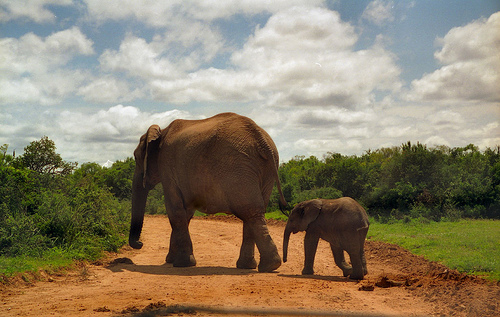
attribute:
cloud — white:
[147, 66, 264, 101]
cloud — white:
[410, 10, 497, 100]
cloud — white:
[236, 10, 360, 67]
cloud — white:
[359, 0, 415, 26]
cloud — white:
[1, 27, 94, 75]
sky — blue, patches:
[1, 1, 499, 175]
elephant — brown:
[127, 111, 292, 273]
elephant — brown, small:
[281, 194, 369, 280]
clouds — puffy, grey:
[405, 21, 498, 103]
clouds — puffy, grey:
[152, 20, 400, 114]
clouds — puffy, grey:
[256, 96, 498, 161]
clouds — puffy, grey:
[96, 22, 227, 87]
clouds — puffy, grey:
[1, 27, 91, 107]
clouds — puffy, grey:
[46, 103, 202, 145]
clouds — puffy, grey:
[1, 137, 137, 197]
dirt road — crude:
[6, 225, 486, 315]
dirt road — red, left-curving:
[0, 211, 495, 315]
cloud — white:
[58, 105, 208, 142]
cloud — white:
[68, 75, 143, 105]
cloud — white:
[277, 107, 375, 124]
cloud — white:
[268, 80, 370, 108]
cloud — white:
[150, 68, 269, 103]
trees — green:
[284, 130, 499, 222]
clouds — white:
[171, 10, 402, 104]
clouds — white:
[6, 28, 80, 112]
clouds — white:
[419, 16, 499, 103]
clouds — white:
[401, 7, 498, 142]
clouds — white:
[228, 6, 393, 128]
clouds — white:
[5, 29, 223, 106]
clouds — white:
[1, 1, 231, 45]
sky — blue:
[156, 18, 289, 64]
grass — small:
[424, 233, 468, 280]